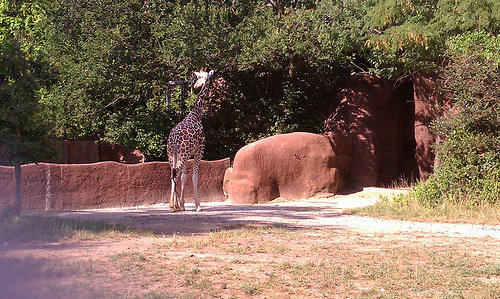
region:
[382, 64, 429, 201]
A door opening to a cave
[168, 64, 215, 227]
A giraffe facing the forest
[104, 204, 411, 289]
Ground with scarttered grass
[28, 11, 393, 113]
A thick green forest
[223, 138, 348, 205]
A clay curved structure wall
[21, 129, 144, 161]
A metal brown gate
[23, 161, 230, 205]
A rectangular clay fance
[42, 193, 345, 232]
shadow of a tree on the ground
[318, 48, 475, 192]
Entrance to the forest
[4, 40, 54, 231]
A tree growing on the way to the forest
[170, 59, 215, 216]
A tall giraffe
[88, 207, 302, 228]
a bare patch of land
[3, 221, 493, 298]
An area of cattered grass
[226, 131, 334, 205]
A large rock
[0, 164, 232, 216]
A rocky wall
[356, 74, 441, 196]
An entrance into a cave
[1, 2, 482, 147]
A thiick bush of shrubs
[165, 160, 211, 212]
A giraffe's legs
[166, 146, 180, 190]
This is a giraffe's tail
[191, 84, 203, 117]
A giraff'es neck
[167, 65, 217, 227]
giraffe standing in its habitat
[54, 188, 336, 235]
trees casting shadows on the ground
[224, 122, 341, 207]
large brown boulder by entrance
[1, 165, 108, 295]
dust stirring up on the ground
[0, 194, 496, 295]
dry grass in the habitat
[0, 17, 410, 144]
greenery on the wall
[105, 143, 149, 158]
leaves casting shadows on wall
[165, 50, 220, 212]
brown and white giraffe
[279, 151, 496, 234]
gravel pathway leading to entrance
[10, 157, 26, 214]
black stripe on retaining wall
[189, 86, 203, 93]
The nose of the giraffe.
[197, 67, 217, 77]
The ears of the giraffe.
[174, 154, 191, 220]
The front left leg of the giraffe.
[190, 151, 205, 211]
The front right leg of the giraffe.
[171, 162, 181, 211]
The left back leg of the giraffe.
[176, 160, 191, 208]
The right back leg of the giraffe.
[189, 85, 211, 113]
The neck area of the giraffe.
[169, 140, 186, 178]
The tail of the giraffe.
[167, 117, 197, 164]
The body area of the giraffe.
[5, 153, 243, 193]
The brown wall in front of the giraffe.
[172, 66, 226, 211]
this is a giraffe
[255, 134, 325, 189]
this is a rock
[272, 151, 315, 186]
the rock is brown in color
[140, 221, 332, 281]
this is the ground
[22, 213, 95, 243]
this is a grass area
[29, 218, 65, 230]
ther grass is green in color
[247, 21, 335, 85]
this is a tree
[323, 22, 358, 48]
the tree has green leaves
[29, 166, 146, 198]
this is a wall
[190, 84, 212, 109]
the neck is long